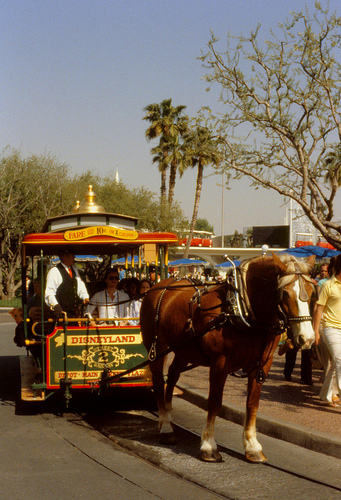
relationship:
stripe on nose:
[293, 278, 315, 341] [271, 296, 314, 371]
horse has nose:
[139, 251, 316, 464] [271, 296, 314, 371]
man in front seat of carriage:
[91, 267, 137, 333] [19, 183, 183, 401]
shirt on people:
[317, 276, 339, 332] [313, 255, 341, 408]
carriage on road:
[19, 183, 183, 401] [0, 420, 153, 496]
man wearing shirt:
[314, 262, 330, 285] [316, 277, 330, 286]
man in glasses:
[84, 268, 130, 327] [106, 275, 119, 281]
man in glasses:
[44, 247, 91, 320] [106, 275, 119, 281]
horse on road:
[139, 251, 316, 464] [47, 379, 309, 496]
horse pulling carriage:
[139, 251, 316, 464] [23, 220, 173, 414]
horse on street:
[112, 225, 288, 417] [0, 323, 340, 498]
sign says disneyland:
[45, 324, 149, 377] [65, 331, 138, 345]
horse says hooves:
[139, 251, 316, 464] [197, 447, 265, 464]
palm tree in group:
[141, 99, 199, 211] [140, 91, 216, 226]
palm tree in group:
[149, 137, 183, 170] [140, 91, 216, 226]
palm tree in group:
[181, 131, 223, 167] [140, 91, 216, 226]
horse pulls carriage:
[139, 251, 316, 464] [9, 208, 182, 408]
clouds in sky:
[103, 143, 340, 235] [4, 2, 337, 233]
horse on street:
[139, 251, 316, 464] [0, 323, 340, 498]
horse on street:
[139, 251, 316, 464] [0, 389, 339, 496]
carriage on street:
[19, 183, 183, 401] [0, 323, 340, 498]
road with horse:
[0, 321, 313, 498] [139, 251, 316, 464]